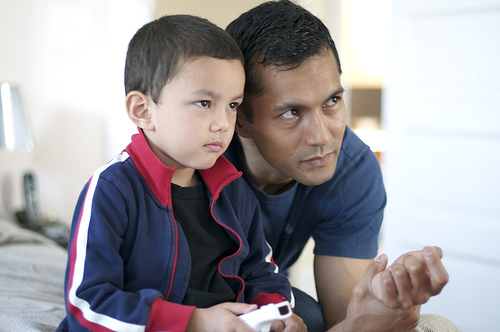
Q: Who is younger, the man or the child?
A: The child is younger than the man.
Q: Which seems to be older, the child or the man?
A: The man is older than the child.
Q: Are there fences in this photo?
A: No, there are no fences.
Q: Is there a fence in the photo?
A: No, there are no fences.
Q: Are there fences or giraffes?
A: No, there are no fences or giraffes.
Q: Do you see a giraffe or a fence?
A: No, there are no fences or giraffes.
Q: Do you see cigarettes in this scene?
A: No, there are no cigarettes.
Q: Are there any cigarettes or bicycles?
A: No, there are no cigarettes or bicycles.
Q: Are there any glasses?
A: No, there are no glasses.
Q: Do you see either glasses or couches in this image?
A: No, there are no glasses or couches.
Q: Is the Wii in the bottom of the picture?
A: Yes, the Wii is in the bottom of the image.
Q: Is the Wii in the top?
A: No, the Wii is in the bottom of the image.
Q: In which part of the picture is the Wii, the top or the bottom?
A: The Wii is in the bottom of the image.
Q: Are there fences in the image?
A: No, there are no fences.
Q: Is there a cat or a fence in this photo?
A: No, there are no fences or cats.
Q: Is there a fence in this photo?
A: No, there are no fences.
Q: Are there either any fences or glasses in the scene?
A: No, there are no fences or glasses.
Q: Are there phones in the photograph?
A: Yes, there is a phone.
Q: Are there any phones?
A: Yes, there is a phone.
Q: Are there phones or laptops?
A: Yes, there is a phone.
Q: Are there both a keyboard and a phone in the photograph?
A: No, there is a phone but no keyboards.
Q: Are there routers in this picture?
A: No, there are no routers.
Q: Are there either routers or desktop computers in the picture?
A: No, there are no routers or desktop computers.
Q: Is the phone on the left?
A: Yes, the phone is on the left of the image.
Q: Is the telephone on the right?
A: No, the telephone is on the left of the image.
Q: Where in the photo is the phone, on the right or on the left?
A: The phone is on the left of the image.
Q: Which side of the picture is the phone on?
A: The phone is on the left of the image.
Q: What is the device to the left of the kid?
A: The device is a phone.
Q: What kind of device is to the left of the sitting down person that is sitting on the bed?
A: The device is a phone.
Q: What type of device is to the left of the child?
A: The device is a phone.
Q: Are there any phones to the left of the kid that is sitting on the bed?
A: Yes, there is a phone to the left of the child.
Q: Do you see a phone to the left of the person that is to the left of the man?
A: Yes, there is a phone to the left of the child.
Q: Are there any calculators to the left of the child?
A: No, there is a phone to the left of the child.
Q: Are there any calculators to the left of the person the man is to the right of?
A: No, there is a phone to the left of the child.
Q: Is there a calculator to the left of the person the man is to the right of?
A: No, there is a phone to the left of the child.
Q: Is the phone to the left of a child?
A: Yes, the phone is to the left of a child.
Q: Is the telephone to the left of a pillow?
A: No, the telephone is to the left of a child.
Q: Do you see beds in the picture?
A: Yes, there is a bed.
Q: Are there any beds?
A: Yes, there is a bed.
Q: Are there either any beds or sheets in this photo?
A: Yes, there is a bed.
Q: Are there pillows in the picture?
A: No, there are no pillows.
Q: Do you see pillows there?
A: No, there are no pillows.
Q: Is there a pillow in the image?
A: No, there are no pillows.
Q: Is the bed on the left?
A: Yes, the bed is on the left of the image.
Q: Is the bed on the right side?
A: No, the bed is on the left of the image.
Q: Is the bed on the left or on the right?
A: The bed is on the left of the image.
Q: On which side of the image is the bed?
A: The bed is on the left of the image.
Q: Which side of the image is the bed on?
A: The bed is on the left of the image.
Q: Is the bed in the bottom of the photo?
A: Yes, the bed is in the bottom of the image.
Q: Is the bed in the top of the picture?
A: No, the bed is in the bottom of the image.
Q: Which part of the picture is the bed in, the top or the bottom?
A: The bed is in the bottom of the image.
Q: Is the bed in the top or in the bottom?
A: The bed is in the bottom of the image.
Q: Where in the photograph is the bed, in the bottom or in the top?
A: The bed is in the bottom of the image.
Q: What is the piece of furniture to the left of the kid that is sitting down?
A: The piece of furniture is a bed.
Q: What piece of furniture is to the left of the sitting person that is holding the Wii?
A: The piece of furniture is a bed.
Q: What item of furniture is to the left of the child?
A: The piece of furniture is a bed.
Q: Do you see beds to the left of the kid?
A: Yes, there is a bed to the left of the kid.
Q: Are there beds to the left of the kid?
A: Yes, there is a bed to the left of the kid.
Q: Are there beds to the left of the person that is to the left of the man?
A: Yes, there is a bed to the left of the kid.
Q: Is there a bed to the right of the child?
A: No, the bed is to the left of the child.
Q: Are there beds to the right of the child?
A: No, the bed is to the left of the child.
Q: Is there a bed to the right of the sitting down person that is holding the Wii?
A: No, the bed is to the left of the child.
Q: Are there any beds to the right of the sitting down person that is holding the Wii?
A: No, the bed is to the left of the child.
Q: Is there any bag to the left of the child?
A: No, there is a bed to the left of the child.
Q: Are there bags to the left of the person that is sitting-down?
A: No, there is a bed to the left of the child.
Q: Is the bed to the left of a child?
A: Yes, the bed is to the left of a child.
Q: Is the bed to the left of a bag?
A: No, the bed is to the left of a child.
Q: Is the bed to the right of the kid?
A: No, the bed is to the left of the kid.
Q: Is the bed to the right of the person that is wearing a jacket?
A: No, the bed is to the left of the kid.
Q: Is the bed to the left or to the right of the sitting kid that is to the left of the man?
A: The bed is to the left of the kid.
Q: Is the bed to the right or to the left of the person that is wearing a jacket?
A: The bed is to the left of the kid.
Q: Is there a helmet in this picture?
A: No, there are no helmets.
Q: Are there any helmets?
A: No, there are no helmets.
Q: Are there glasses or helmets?
A: No, there are no helmets or glasses.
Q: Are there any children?
A: Yes, there is a child.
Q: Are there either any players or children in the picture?
A: Yes, there is a child.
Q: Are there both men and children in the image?
A: Yes, there are both a child and a man.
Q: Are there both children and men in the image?
A: Yes, there are both a child and a man.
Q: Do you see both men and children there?
A: Yes, there are both a child and a man.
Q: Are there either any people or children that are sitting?
A: Yes, the child is sitting.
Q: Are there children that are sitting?
A: Yes, there is a child that is sitting.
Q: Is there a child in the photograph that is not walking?
A: Yes, there is a child that is sitting.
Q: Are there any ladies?
A: No, there are no ladies.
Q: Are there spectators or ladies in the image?
A: No, there are no ladies or spectators.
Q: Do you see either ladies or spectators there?
A: No, there are no ladies or spectators.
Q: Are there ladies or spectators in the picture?
A: No, there are no ladies or spectators.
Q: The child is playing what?
A: The child is playing wii.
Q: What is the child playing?
A: The child is playing wii.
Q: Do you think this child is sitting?
A: Yes, the child is sitting.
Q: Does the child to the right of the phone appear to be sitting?
A: Yes, the kid is sitting.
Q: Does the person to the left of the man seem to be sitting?
A: Yes, the kid is sitting.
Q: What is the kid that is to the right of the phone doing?
A: The child is sitting.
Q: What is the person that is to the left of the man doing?
A: The child is sitting.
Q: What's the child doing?
A: The child is sitting.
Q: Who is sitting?
A: The kid is sitting.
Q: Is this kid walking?
A: No, the kid is sitting.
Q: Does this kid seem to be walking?
A: No, the kid is sitting.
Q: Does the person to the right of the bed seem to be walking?
A: No, the kid is sitting.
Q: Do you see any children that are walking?
A: No, there is a child but he is sitting.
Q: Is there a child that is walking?
A: No, there is a child but he is sitting.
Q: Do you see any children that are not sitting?
A: No, there is a child but he is sitting.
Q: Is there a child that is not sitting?
A: No, there is a child but he is sitting.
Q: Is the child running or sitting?
A: The child is sitting.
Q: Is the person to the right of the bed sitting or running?
A: The child is sitting.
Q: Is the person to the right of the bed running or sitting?
A: The child is sitting.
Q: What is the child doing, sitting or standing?
A: The child is sitting.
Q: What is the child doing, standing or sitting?
A: The child is sitting.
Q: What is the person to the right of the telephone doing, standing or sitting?
A: The child is sitting.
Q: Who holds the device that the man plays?
A: The kid holds the Wii.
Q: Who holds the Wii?
A: The kid holds the Wii.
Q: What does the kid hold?
A: The kid holds the Wii.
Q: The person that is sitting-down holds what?
A: The kid holds the Wii.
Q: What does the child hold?
A: The kid holds the Wii.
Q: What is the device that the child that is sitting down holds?
A: The device is a Wii.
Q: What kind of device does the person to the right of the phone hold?
A: The kid holds the Wii.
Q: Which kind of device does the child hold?
A: The kid holds the Wii.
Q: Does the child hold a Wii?
A: Yes, the child holds a Wii.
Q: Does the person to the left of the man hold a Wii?
A: Yes, the child holds a Wii.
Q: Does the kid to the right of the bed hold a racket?
A: No, the child holds a Wii.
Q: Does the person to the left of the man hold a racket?
A: No, the child holds a Wii.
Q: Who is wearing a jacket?
A: The kid is wearing a jacket.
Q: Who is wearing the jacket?
A: The kid is wearing a jacket.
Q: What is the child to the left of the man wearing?
A: The child is wearing a jacket.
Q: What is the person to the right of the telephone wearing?
A: The child is wearing a jacket.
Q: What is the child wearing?
A: The child is wearing a jacket.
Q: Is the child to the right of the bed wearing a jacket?
A: Yes, the kid is wearing a jacket.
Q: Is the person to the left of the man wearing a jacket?
A: Yes, the kid is wearing a jacket.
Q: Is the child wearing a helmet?
A: No, the child is wearing a jacket.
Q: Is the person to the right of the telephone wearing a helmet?
A: No, the child is wearing a jacket.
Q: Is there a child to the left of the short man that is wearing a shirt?
A: Yes, there is a child to the left of the man.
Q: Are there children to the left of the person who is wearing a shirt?
A: Yes, there is a child to the left of the man.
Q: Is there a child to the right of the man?
A: No, the child is to the left of the man.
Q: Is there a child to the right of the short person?
A: No, the child is to the left of the man.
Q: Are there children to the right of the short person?
A: No, the child is to the left of the man.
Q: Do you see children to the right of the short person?
A: No, the child is to the left of the man.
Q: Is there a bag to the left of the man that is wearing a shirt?
A: No, there is a child to the left of the man.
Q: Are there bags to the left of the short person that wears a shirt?
A: No, there is a child to the left of the man.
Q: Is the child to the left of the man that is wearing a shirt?
A: Yes, the child is to the left of the man.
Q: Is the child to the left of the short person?
A: Yes, the child is to the left of the man.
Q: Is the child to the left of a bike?
A: No, the child is to the left of the man.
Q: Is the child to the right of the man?
A: No, the child is to the left of the man.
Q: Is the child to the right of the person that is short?
A: No, the child is to the left of the man.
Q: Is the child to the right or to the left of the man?
A: The child is to the left of the man.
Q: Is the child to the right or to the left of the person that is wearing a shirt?
A: The child is to the left of the man.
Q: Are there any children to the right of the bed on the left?
A: Yes, there is a child to the right of the bed.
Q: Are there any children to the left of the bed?
A: No, the child is to the right of the bed.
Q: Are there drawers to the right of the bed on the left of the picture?
A: No, there is a child to the right of the bed.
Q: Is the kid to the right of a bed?
A: Yes, the kid is to the right of a bed.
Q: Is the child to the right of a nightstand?
A: No, the child is to the right of a bed.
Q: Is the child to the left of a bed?
A: No, the child is to the right of a bed.